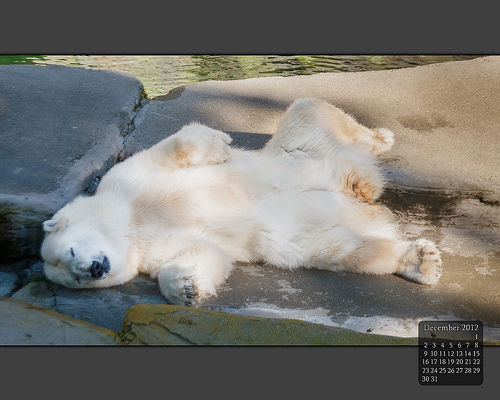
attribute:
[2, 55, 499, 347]
pavement — grey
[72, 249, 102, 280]
nose — black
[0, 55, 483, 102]
water — green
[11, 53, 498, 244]
rocks — slabs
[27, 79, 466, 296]
bear — sunbathing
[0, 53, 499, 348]
scene — outdoors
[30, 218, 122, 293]
face — black, white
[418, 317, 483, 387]
calendar — black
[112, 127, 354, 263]
fur — white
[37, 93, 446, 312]
bear — white, laying down 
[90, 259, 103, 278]
nose — black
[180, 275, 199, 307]
claws — sharp